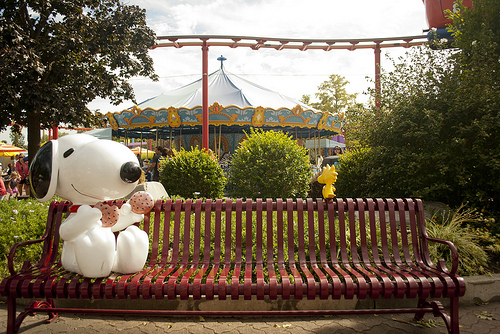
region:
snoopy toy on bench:
[22, 125, 156, 279]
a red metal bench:
[4, 191, 469, 332]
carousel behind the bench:
[97, 48, 352, 193]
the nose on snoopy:
[117, 158, 144, 188]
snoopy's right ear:
[27, 135, 62, 209]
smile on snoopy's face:
[64, 180, 116, 207]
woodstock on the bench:
[316, 160, 341, 205]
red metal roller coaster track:
[123, 24, 452, 59]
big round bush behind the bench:
[229, 120, 314, 201]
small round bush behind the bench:
[156, 145, 234, 205]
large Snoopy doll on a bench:
[29, 133, 151, 277]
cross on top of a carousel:
[216, 54, 226, 71]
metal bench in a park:
[7, 196, 466, 326]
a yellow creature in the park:
[316, 163, 338, 201]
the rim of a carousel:
[97, 104, 347, 131]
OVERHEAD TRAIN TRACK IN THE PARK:
[148, 28, 448, 50]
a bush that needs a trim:
[224, 129, 314, 196]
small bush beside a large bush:
[156, 143, 224, 198]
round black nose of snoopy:
[120, 160, 140, 184]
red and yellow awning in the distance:
[0, 143, 26, 156]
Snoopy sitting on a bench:
[28, 133, 160, 280]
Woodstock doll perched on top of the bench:
[317, 162, 338, 202]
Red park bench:
[3, 191, 465, 331]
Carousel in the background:
[106, 51, 348, 165]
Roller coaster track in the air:
[135, 27, 447, 52]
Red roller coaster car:
[423, 0, 474, 55]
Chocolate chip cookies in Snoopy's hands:
[96, 188, 153, 227]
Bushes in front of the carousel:
[158, 127, 313, 203]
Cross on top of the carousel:
[216, 49, 228, 72]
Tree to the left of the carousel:
[1, 0, 158, 198]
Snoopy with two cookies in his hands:
[27, 130, 160, 275]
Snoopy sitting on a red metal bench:
[4, 133, 467, 331]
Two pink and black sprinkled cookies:
[95, 193, 159, 225]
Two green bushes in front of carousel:
[158, 132, 310, 196]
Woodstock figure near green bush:
[316, 162, 338, 197]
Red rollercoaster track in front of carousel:
[148, 32, 438, 154]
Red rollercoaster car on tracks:
[418, 0, 489, 48]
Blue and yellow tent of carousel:
[106, 53, 346, 141]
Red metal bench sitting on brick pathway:
[3, 200, 465, 330]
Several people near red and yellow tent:
[1, 139, 31, 197]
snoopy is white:
[65, 139, 153, 286]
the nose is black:
[122, 158, 142, 187]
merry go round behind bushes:
[132, 90, 307, 198]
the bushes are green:
[177, 143, 309, 196]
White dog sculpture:
[27, 125, 157, 277]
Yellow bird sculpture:
[305, 157, 339, 201]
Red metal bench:
[2, 198, 472, 332]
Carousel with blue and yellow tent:
[104, 48, 340, 172]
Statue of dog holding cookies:
[27, 128, 154, 275]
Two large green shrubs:
[155, 129, 314, 200]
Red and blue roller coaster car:
[409, 0, 485, 49]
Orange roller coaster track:
[30, 26, 431, 171]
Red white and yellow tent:
[0, 138, 26, 158]